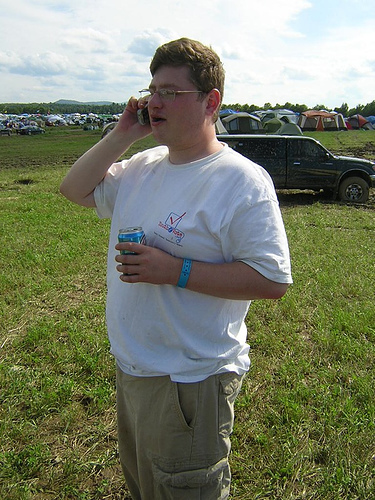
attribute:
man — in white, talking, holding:
[58, 38, 292, 499]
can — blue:
[116, 226, 146, 277]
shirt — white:
[93, 140, 292, 382]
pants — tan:
[115, 357, 249, 495]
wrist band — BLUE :
[176, 258, 193, 287]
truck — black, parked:
[213, 135, 374, 202]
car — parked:
[15, 124, 47, 137]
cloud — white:
[2, 5, 125, 71]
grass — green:
[1, 128, 374, 499]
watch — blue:
[176, 258, 192, 291]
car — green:
[218, 136, 373, 201]